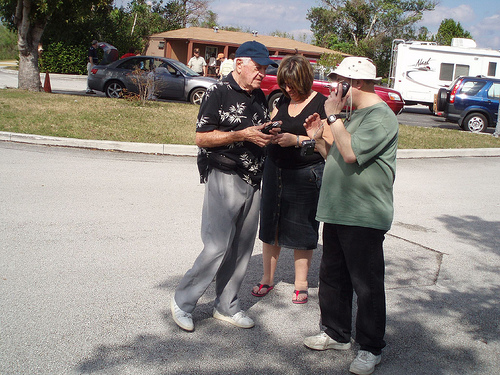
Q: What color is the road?
A: Grey.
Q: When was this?
A: Daytime.